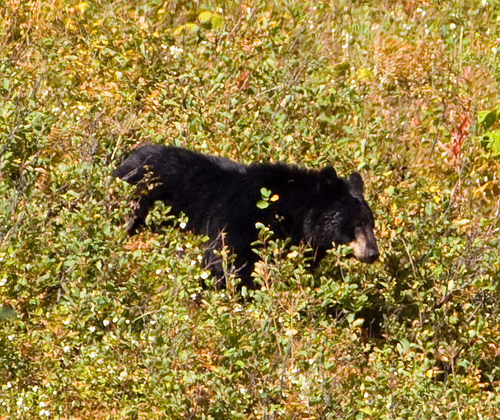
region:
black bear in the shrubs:
[103, 135, 411, 341]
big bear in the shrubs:
[66, 137, 412, 355]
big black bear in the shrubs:
[86, 136, 396, 363]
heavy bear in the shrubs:
[80, 138, 397, 347]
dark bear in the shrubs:
[80, 134, 400, 351]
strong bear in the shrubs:
[80, 133, 398, 356]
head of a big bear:
[296, 162, 392, 286]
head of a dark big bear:
[291, 154, 391, 304]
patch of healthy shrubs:
[28, 289, 266, 408]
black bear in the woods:
[115, 118, 385, 299]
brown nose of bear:
[347, 226, 381, 268]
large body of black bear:
[100, 123, 318, 281]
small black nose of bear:
[357, 248, 382, 268]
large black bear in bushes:
[67, 111, 401, 331]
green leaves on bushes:
[1, 242, 165, 379]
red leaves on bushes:
[435, 113, 472, 171]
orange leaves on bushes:
[12, 28, 97, 89]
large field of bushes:
[18, 19, 452, 416]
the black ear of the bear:
[318, 166, 337, 198]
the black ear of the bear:
[350, 172, 366, 198]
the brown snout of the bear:
[348, 225, 378, 265]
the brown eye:
[353, 218, 363, 228]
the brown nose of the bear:
[366, 246, 380, 259]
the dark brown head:
[300, 189, 376, 261]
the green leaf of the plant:
[223, 347, 235, 357]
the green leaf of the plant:
[235, 359, 247, 370]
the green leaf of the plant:
[258, 356, 268, 364]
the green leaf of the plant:
[347, 313, 355, 325]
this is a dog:
[110, 85, 395, 282]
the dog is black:
[79, 97, 449, 310]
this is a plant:
[238, 294, 304, 401]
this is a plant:
[311, 314, 361, 416]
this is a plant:
[104, 320, 154, 411]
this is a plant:
[141, 207, 217, 323]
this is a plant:
[399, 250, 451, 369]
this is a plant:
[264, 272, 331, 390]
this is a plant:
[169, 312, 238, 404]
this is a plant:
[89, 215, 149, 312]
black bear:
[100, 113, 400, 343]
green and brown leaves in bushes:
[25, 268, 75, 310]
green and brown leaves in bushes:
[174, 359, 246, 400]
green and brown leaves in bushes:
[305, 346, 366, 398]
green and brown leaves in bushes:
[377, 318, 437, 389]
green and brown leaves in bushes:
[28, 218, 85, 280]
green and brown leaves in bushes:
[85, 39, 156, 91]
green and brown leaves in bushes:
[257, 59, 309, 116]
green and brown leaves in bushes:
[311, 1, 386, 61]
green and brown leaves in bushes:
[394, 81, 478, 171]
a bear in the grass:
[76, 110, 399, 381]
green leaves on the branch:
[275, 362, 287, 392]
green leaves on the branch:
[365, 398, 394, 415]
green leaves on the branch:
[442, 307, 488, 377]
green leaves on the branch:
[407, 272, 445, 315]